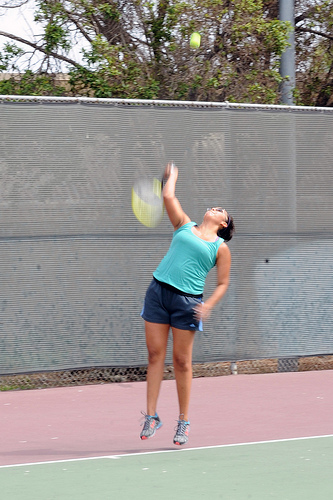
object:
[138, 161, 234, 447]
woman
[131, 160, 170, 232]
racket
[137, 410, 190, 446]
shoes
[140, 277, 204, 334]
shorts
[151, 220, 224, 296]
tank top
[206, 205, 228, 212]
glasses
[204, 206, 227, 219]
face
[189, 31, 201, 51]
tennis ball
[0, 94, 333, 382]
fence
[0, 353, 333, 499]
court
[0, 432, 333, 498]
court portion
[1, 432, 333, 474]
stripe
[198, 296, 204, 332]
trim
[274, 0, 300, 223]
pole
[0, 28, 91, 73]
brach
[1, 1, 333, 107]
tree